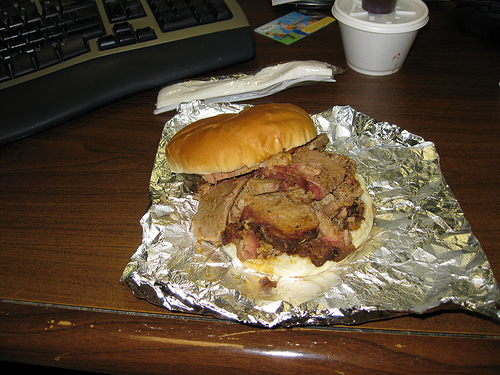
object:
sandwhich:
[162, 101, 376, 278]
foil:
[116, 98, 498, 333]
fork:
[152, 75, 338, 116]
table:
[1, 40, 499, 370]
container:
[329, 0, 433, 77]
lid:
[330, 0, 431, 35]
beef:
[188, 147, 366, 268]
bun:
[162, 102, 318, 176]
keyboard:
[0, 0, 253, 142]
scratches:
[12, 317, 248, 363]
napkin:
[156, 60, 334, 109]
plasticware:
[153, 59, 348, 116]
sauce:
[360, 0, 398, 15]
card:
[253, 10, 337, 47]